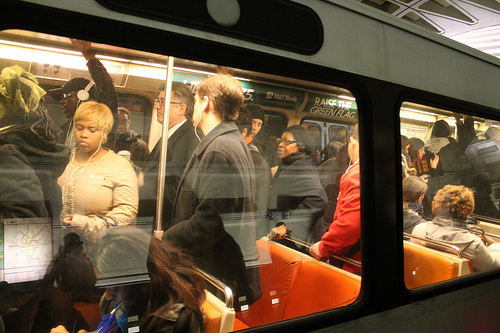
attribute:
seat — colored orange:
[258, 224, 378, 317]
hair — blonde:
[67, 99, 115, 142]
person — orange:
[303, 118, 371, 274]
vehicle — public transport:
[0, 0, 496, 329]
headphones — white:
[184, 94, 214, 146]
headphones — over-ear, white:
[193, 102, 207, 142]